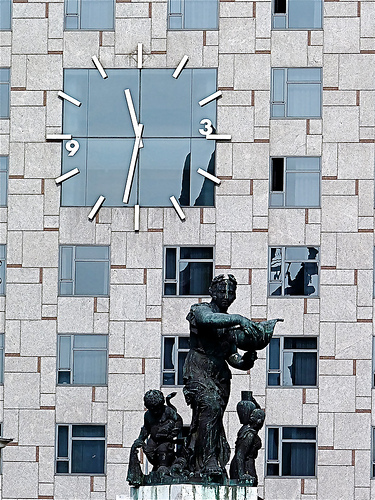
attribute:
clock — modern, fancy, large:
[42, 38, 235, 237]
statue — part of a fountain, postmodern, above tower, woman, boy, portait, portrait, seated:
[102, 257, 284, 487]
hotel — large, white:
[3, 1, 372, 499]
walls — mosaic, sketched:
[221, 57, 365, 334]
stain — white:
[217, 268, 231, 293]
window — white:
[253, 61, 337, 123]